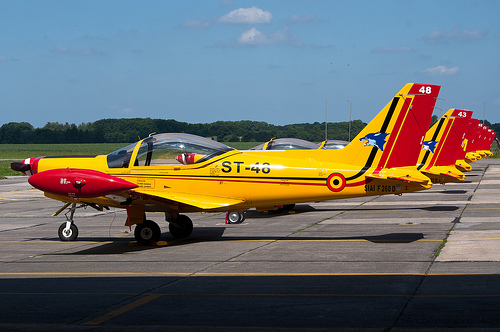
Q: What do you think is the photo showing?
A: It is showing a runway.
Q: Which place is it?
A: It is a runway.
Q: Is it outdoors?
A: Yes, it is outdoors.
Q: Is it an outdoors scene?
A: Yes, it is outdoors.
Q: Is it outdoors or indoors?
A: It is outdoors.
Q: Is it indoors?
A: No, it is outdoors.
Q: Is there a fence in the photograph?
A: No, there are no fences.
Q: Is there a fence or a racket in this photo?
A: No, there are no fences or rackets.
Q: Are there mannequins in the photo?
A: No, there are no mannequins.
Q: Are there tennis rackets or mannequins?
A: No, there are no mannequins or tennis rackets.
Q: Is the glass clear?
A: Yes, the glass is clear.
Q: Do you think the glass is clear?
A: Yes, the glass is clear.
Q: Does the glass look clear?
A: Yes, the glass is clear.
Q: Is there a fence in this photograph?
A: No, there are no fences.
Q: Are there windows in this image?
A: Yes, there is a window.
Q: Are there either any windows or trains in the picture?
A: Yes, there is a window.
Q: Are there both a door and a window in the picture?
A: No, there is a window but no doors.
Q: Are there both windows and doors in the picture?
A: No, there is a window but no doors.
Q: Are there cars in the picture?
A: No, there are no cars.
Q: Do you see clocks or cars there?
A: No, there are no cars or clocks.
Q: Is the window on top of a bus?
A: No, the window is on top of the airplane.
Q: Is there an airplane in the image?
A: Yes, there is an airplane.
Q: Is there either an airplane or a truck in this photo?
A: Yes, there is an airplane.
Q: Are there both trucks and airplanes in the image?
A: No, there is an airplane but no trucks.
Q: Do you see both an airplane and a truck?
A: No, there is an airplane but no trucks.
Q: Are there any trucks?
A: No, there are no trucks.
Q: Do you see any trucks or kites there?
A: No, there are no trucks or kites.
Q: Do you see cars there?
A: No, there are no cars.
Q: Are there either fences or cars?
A: No, there are no cars or fences.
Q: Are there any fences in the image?
A: No, there are no fences.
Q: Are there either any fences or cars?
A: No, there are no fences or cars.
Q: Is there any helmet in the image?
A: No, there are no helmets.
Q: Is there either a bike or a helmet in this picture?
A: No, there are no helmets or bikes.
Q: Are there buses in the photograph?
A: No, there are no buses.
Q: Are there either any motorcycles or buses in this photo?
A: No, there are no buses or motorcycles.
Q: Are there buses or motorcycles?
A: No, there are no buses or motorcycles.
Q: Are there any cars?
A: No, there are no cars.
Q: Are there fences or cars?
A: No, there are no cars or fences.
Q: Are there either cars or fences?
A: No, there are no cars or fences.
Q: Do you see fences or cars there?
A: No, there are no cars or fences.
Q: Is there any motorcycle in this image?
A: No, there are no motorcycles.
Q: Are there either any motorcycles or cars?
A: No, there are no motorcycles or cars.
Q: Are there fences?
A: No, there are no fences.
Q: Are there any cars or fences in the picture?
A: No, there are no fences or cars.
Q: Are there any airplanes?
A: Yes, there are airplanes.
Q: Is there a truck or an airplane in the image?
A: Yes, there are airplanes.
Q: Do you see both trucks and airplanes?
A: No, there are airplanes but no trucks.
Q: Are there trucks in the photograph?
A: No, there are no trucks.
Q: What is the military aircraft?
A: The aircraft is airplanes.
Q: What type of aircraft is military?
A: The aircraft is airplanes.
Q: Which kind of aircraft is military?
A: The aircraft is airplanes.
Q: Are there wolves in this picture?
A: Yes, there is a wolf.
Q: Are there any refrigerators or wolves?
A: Yes, there is a wolf.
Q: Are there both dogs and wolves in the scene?
A: No, there is a wolf but no dogs.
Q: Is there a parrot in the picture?
A: No, there are no parrots.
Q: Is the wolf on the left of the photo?
A: No, the wolf is on the right of the image.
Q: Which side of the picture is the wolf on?
A: The wolf is on the right of the image.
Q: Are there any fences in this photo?
A: No, there are no fences.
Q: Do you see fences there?
A: No, there are no fences.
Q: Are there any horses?
A: No, there are no horses.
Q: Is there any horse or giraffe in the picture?
A: No, there are no horses or giraffes.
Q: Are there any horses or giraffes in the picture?
A: No, there are no horses or giraffes.